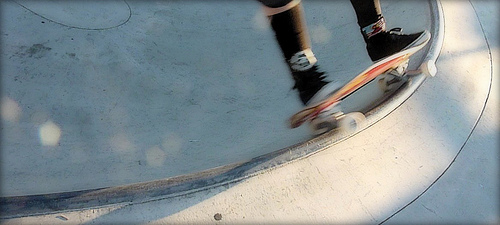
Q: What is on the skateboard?
A: Two legs.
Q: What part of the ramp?
A: Edge.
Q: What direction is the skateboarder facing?
A: Up.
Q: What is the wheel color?
A: White.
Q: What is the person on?
A: Skateboard.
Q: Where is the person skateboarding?
A: Pool.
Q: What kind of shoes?
A: Sneakers.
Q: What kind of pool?
A: Concrete.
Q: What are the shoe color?
A: Black.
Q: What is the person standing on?
A: Skateboard.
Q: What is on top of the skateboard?
A: Two feet.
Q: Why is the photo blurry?
A: Skateboard is moving.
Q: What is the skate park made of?
A: Cement.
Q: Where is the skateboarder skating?
A: Around the rim.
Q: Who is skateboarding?
A: The skateboarder.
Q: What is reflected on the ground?
A: Shadows from the trees.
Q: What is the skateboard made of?
A: Wood.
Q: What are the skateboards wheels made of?
A: Resin.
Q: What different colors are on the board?
A: Red, white and yellow.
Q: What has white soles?
A: The black converse sneakers.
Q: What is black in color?
A: The sneaker.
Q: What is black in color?
A: The sneaker.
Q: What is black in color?
A: The sneaker.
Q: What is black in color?
A: The sneaker.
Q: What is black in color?
A: The sneaker.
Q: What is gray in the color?
A: The ramp.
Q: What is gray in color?
A: The ramp.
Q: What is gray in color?
A: The ramp.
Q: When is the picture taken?
A: Daytime.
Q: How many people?
A: One.